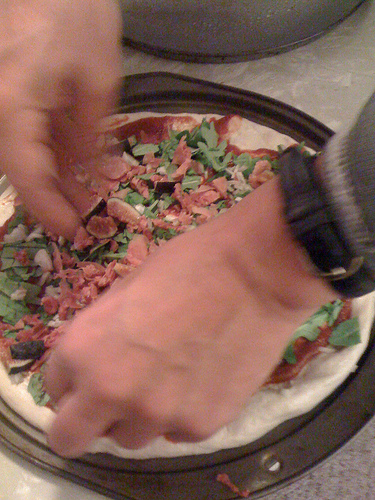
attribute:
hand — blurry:
[45, 154, 345, 461]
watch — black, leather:
[277, 146, 375, 299]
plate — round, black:
[120, 2, 374, 64]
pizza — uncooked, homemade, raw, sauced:
[0, 113, 375, 461]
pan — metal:
[1, 71, 372, 499]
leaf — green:
[198, 121, 228, 170]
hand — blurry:
[0, 1, 124, 243]